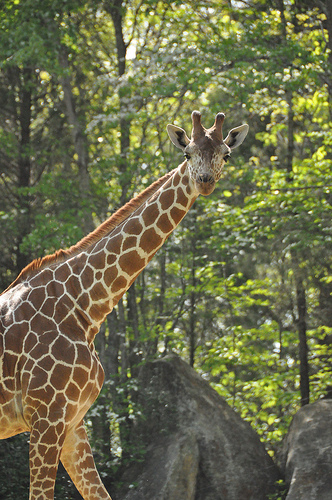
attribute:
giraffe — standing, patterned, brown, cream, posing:
[0, 110, 249, 499]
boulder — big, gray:
[105, 354, 282, 499]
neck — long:
[79, 159, 200, 341]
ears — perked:
[165, 123, 248, 152]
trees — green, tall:
[1, 0, 331, 499]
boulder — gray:
[272, 396, 332, 499]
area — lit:
[0, 0, 330, 500]